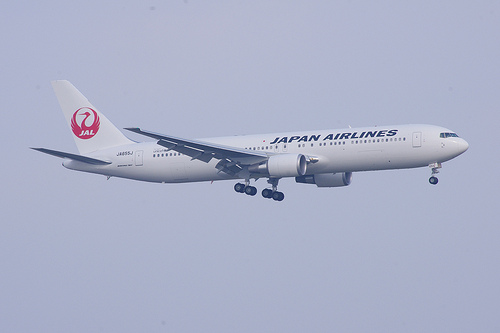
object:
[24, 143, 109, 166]
stabilizer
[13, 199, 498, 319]
no objects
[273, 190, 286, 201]
tires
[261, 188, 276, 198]
tires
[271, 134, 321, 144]
words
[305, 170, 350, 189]
engine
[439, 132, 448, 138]
window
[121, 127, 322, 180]
wing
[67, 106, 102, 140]
emblem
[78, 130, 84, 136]
letters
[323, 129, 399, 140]
words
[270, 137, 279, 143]
lettering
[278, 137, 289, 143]
lettering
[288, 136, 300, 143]
lettering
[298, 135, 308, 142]
lettering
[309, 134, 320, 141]
lettering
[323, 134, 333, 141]
lettering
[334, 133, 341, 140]
lettering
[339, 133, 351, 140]
lettering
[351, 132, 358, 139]
lettering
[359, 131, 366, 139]
lettering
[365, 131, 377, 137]
lettering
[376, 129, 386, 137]
lettering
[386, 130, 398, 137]
lettering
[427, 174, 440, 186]
front wheels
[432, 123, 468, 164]
cockpit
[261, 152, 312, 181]
engine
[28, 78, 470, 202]
airplane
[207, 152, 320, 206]
gear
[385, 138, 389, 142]
windows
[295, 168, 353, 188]
jet engines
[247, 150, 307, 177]
jet engines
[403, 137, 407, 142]
window line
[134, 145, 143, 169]
door